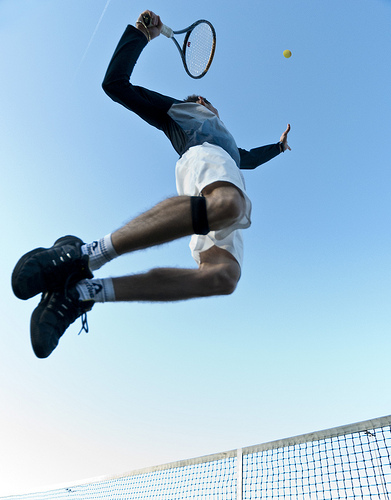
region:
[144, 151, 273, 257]
White shorts on tennis player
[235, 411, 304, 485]
Net on the tennis court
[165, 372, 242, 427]
Clear blue sky above the tennis court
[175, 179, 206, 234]
Knee band on the tennis player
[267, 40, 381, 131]
Tennis ball in the sky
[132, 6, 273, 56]
Man swinging the tennis racket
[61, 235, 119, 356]
White socks on the tennis player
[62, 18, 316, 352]
Jumping to hit the ball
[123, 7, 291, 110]
Tennis racket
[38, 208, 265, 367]
Jumping in the air to hit the tennis ball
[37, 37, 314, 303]
Tennis player in the air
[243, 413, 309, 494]
Tennis net on the court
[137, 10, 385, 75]
Tennis racket hitting the ball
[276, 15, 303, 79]
Tennis ball in the sky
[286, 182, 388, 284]
Blue clear sky over the tennis court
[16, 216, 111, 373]
Tennis sneakers on the player's feet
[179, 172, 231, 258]
Knee band on the tennis player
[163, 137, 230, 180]
Tennis player has white shirts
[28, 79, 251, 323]
Player in the air jumping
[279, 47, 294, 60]
Tennis ball in the air.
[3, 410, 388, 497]
Tennis net underneath the player.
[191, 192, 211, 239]
Black band under the player's knee.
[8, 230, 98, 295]
The player's sneaker on the left.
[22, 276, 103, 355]
The player's sneaker on the right.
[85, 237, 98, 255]
The black design on the player's left sock.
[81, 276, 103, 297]
The design on the player's right sock.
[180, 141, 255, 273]
The white shorts worn by the player.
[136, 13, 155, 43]
The bracelet on the player's wrist.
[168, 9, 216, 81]
The tennis racket in the player's hand.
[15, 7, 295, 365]
Tennis player is in the air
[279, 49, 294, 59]
Tennis ball is in the air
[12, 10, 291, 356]
tennis player is jumpiing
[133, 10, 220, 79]
tennis player holds racket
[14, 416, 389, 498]
Net is in front of tennis player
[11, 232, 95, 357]
player wears black sneakers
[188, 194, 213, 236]
player has black band around leg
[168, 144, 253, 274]
tennis player wears white shorts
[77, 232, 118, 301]
tennis player has white socks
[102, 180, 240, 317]
tennis player has hairy legs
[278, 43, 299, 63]
yellow tennis ball in the air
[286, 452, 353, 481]
strings on court net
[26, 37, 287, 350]
man jumping in the air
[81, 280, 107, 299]
logo on white socks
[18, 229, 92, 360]
black sneakers on player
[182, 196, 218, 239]
black band on leg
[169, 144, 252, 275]
white shorts on tennis player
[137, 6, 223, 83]
man's hand on racquet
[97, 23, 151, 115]
long dark sleeves on player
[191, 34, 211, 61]
strings on tennis racquet